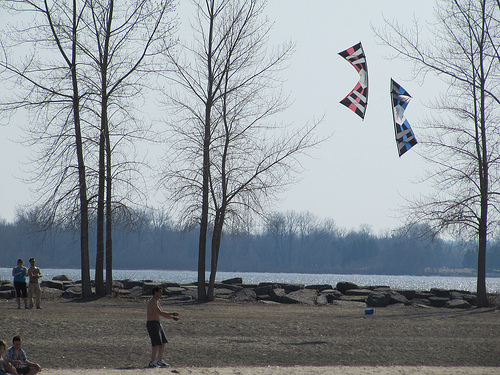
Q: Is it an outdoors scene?
A: Yes, it is outdoors.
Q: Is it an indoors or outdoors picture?
A: It is outdoors.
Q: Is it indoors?
A: No, it is outdoors.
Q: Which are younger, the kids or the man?
A: The kids are younger than the man.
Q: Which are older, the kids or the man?
A: The man are older than the kids.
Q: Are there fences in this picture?
A: No, there are no fences.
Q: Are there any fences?
A: No, there are no fences.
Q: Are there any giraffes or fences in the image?
A: No, there are no fences or giraffes.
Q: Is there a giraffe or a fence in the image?
A: No, there are no fences or giraffes.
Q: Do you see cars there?
A: No, there are no cars.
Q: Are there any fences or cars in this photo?
A: No, there are no cars or fences.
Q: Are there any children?
A: Yes, there are children.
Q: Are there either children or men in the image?
A: Yes, there are children.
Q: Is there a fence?
A: No, there are no fences.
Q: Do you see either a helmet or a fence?
A: No, there are no fences or helmets.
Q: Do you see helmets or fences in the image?
A: No, there are no fences or helmets.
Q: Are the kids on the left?
A: Yes, the kids are on the left of the image.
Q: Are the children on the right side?
A: No, the children are on the left of the image.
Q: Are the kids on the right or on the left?
A: The kids are on the left of the image.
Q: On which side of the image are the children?
A: The children are on the left of the image.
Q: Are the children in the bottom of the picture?
A: Yes, the children are in the bottom of the image.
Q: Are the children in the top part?
A: No, the children are in the bottom of the image.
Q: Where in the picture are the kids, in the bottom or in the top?
A: The kids are in the bottom of the image.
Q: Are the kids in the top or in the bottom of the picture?
A: The kids are in the bottom of the image.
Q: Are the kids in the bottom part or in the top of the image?
A: The kids are in the bottom of the image.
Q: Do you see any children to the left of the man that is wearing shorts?
A: Yes, there are children to the left of the man.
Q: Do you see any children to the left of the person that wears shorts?
A: Yes, there are children to the left of the man.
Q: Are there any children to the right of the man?
A: No, the children are to the left of the man.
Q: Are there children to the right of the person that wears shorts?
A: No, the children are to the left of the man.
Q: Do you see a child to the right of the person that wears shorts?
A: No, the children are to the left of the man.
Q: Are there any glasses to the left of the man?
A: No, there are children to the left of the man.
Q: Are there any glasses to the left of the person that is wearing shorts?
A: No, there are children to the left of the man.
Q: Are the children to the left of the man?
A: Yes, the children are to the left of the man.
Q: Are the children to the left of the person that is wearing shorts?
A: Yes, the children are to the left of the man.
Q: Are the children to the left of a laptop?
A: No, the children are to the left of the man.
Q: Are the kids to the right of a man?
A: No, the kids are to the left of a man.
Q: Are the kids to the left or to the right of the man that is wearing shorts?
A: The kids are to the left of the man.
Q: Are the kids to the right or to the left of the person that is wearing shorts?
A: The kids are to the left of the man.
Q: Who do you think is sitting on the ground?
A: The children are sitting on the ground.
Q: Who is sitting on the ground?
A: The children are sitting on the ground.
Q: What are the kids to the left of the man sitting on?
A: The kids are sitting on the ground.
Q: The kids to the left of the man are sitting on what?
A: The kids are sitting on the ground.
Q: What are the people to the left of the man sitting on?
A: The kids are sitting on the ground.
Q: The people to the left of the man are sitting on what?
A: The kids are sitting on the ground.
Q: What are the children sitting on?
A: The kids are sitting on the ground.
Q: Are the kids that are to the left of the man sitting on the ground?
A: Yes, the kids are sitting on the ground.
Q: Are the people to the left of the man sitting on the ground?
A: Yes, the kids are sitting on the ground.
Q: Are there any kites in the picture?
A: Yes, there is a kite.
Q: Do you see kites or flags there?
A: Yes, there is a kite.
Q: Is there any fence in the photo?
A: No, there are no fences.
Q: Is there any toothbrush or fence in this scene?
A: No, there are no fences or toothbrushes.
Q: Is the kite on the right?
A: Yes, the kite is on the right of the image.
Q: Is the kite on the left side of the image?
A: No, the kite is on the right of the image.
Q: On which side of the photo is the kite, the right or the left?
A: The kite is on the right of the image.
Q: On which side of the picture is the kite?
A: The kite is on the right of the image.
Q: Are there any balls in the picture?
A: No, there are no balls.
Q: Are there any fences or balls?
A: No, there are no balls or fences.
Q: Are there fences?
A: No, there are no fences.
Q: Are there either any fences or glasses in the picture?
A: No, there are no fences or glasses.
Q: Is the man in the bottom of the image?
A: Yes, the man is in the bottom of the image.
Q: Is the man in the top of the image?
A: No, the man is in the bottom of the image.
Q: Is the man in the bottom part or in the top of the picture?
A: The man is in the bottom of the image.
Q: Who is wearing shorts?
A: The man is wearing shorts.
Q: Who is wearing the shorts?
A: The man is wearing shorts.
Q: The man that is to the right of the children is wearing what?
A: The man is wearing shorts.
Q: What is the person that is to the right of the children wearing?
A: The man is wearing shorts.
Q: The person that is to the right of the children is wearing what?
A: The man is wearing shorts.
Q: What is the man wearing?
A: The man is wearing shorts.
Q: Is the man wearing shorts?
A: Yes, the man is wearing shorts.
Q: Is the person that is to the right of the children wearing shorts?
A: Yes, the man is wearing shorts.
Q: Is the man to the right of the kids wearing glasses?
A: No, the man is wearing shorts.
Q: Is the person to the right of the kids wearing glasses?
A: No, the man is wearing shorts.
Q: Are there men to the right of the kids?
A: Yes, there is a man to the right of the kids.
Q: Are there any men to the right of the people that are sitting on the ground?
A: Yes, there is a man to the right of the kids.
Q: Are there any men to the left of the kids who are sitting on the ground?
A: No, the man is to the right of the kids.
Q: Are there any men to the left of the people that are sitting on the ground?
A: No, the man is to the right of the kids.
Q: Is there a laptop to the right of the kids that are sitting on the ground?
A: No, there is a man to the right of the kids.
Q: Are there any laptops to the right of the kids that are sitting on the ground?
A: No, there is a man to the right of the kids.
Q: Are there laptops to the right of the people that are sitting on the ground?
A: No, there is a man to the right of the kids.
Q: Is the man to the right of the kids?
A: Yes, the man is to the right of the kids.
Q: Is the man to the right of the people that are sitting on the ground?
A: Yes, the man is to the right of the kids.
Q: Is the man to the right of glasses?
A: No, the man is to the right of the kids.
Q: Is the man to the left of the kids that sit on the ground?
A: No, the man is to the right of the children.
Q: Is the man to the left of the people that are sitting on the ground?
A: No, the man is to the right of the children.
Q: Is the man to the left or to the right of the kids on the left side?
A: The man is to the right of the children.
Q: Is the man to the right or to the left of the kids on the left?
A: The man is to the right of the children.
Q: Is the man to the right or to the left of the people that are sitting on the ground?
A: The man is to the right of the children.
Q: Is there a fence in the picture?
A: No, there are no fences.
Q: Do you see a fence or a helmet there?
A: No, there are no fences or helmets.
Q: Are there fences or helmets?
A: No, there are no fences or helmets.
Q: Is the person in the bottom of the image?
A: Yes, the person is in the bottom of the image.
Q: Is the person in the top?
A: No, the person is in the bottom of the image.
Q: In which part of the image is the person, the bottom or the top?
A: The person is in the bottom of the image.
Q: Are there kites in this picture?
A: Yes, there is a kite.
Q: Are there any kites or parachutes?
A: Yes, there is a kite.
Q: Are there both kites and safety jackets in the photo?
A: No, there is a kite but no safety jackets.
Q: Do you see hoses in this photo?
A: No, there are no hoses.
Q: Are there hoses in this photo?
A: No, there are no hoses.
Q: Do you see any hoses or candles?
A: No, there are no hoses or candles.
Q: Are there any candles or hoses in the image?
A: No, there are no hoses or candles.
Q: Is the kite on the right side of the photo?
A: Yes, the kite is on the right of the image.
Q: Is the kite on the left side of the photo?
A: No, the kite is on the right of the image.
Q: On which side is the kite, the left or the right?
A: The kite is on the right of the image.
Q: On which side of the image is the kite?
A: The kite is on the right of the image.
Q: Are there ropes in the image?
A: No, there are no ropes.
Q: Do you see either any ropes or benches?
A: No, there are no ropes or benches.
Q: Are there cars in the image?
A: No, there are no cars.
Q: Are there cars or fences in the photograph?
A: No, there are no cars or fences.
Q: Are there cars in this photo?
A: No, there are no cars.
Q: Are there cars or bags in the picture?
A: No, there are no cars or bags.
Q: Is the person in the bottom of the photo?
A: Yes, the person is in the bottom of the image.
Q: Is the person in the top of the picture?
A: No, the person is in the bottom of the image.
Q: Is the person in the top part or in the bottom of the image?
A: The person is in the bottom of the image.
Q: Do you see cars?
A: No, there are no cars.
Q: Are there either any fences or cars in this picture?
A: No, there are no cars or fences.